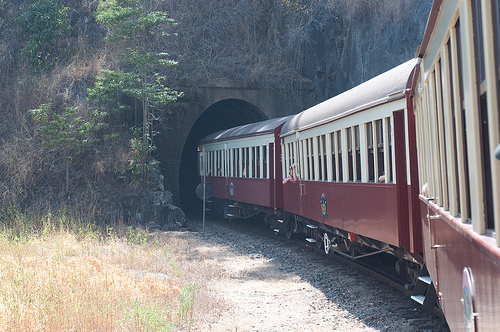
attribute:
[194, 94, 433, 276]
train — for passenger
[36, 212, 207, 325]
weeds — tan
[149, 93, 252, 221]
archway — dark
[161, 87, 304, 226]
tunnel —  concrete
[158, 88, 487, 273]
train — for passenger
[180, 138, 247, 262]
pole —  metal 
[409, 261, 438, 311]
steps —  black,  metal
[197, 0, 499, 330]
red train —  red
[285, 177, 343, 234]
sign — circular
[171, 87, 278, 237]
train tunnel — arched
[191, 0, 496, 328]
train — for passenger, passenger train, red and white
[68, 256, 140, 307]
dead grass —  dead 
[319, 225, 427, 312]
train tracks —  for train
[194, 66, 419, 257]
train —  red and white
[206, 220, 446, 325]
track — railroad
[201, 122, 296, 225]
train car — passenger